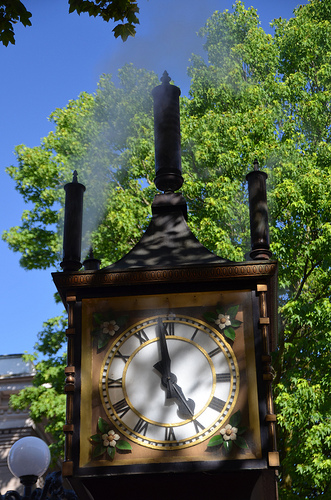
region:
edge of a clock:
[267, 404, 285, 429]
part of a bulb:
[28, 460, 34, 471]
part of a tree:
[299, 413, 309, 436]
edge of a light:
[26, 428, 27, 455]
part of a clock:
[201, 384, 216, 399]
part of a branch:
[298, 397, 308, 412]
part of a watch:
[164, 376, 173, 397]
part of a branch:
[295, 334, 312, 353]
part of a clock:
[3, 420, 17, 441]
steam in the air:
[52, 8, 217, 252]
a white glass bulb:
[7, 436, 47, 475]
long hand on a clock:
[156, 316, 174, 396]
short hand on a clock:
[155, 360, 195, 419]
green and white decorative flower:
[209, 410, 251, 453]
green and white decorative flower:
[205, 302, 244, 338]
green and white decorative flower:
[88, 418, 129, 463]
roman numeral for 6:
[163, 425, 178, 442]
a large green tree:
[11, 8, 330, 498]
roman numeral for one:
[188, 325, 201, 341]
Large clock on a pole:
[55, 262, 274, 469]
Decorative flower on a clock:
[198, 409, 249, 453]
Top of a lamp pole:
[5, 431, 59, 489]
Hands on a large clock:
[147, 311, 205, 424]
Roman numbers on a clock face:
[103, 315, 231, 446]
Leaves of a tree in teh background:
[211, 206, 298, 286]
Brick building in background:
[8, 403, 63, 458]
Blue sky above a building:
[6, 256, 55, 325]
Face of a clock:
[78, 310, 264, 444]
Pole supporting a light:
[16, 468, 34, 494]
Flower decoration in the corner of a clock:
[84, 418, 127, 460]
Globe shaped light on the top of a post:
[7, 437, 47, 474]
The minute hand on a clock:
[153, 316, 176, 396]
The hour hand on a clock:
[161, 380, 198, 419]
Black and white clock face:
[101, 315, 238, 449]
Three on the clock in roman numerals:
[214, 368, 230, 383]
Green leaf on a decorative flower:
[205, 433, 218, 449]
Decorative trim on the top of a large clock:
[239, 264, 272, 272]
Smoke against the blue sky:
[152, 35, 191, 55]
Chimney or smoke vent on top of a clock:
[154, 70, 180, 187]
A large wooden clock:
[63, 253, 286, 470]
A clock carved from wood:
[66, 315, 265, 468]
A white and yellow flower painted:
[98, 423, 122, 452]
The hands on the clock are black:
[151, 330, 198, 424]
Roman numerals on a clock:
[104, 334, 243, 433]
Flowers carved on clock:
[178, 402, 250, 456]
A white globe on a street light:
[6, 433, 50, 494]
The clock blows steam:
[46, 165, 135, 272]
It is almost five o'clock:
[145, 302, 212, 450]